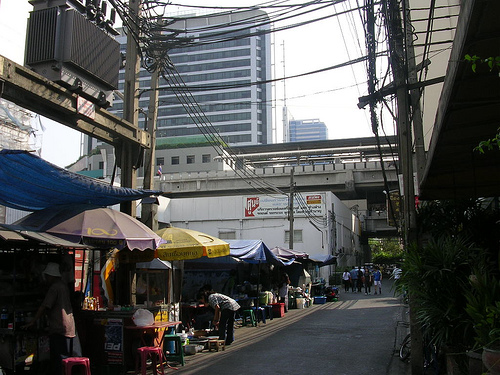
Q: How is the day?
A: Sunny.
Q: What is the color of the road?
A: Grey.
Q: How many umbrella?
A: 2.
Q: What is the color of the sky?
A: White.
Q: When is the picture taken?
A: Daytime.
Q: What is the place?
A: Marketplace.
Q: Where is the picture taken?
A: On the street.